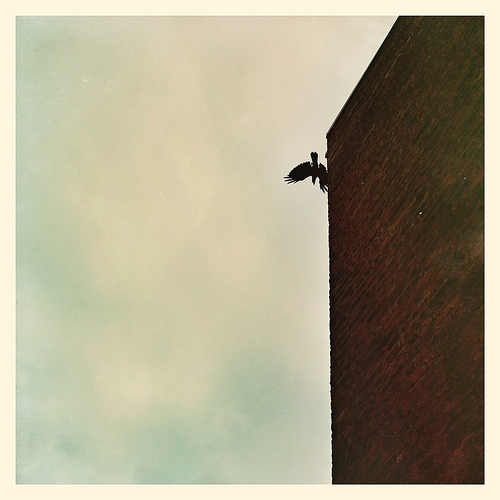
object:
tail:
[310, 151, 318, 168]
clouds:
[41, 49, 234, 408]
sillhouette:
[247, 191, 329, 269]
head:
[311, 175, 317, 186]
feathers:
[283, 173, 303, 184]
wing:
[283, 160, 311, 185]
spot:
[414, 203, 423, 222]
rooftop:
[305, 23, 473, 133]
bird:
[283, 150, 335, 196]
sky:
[10, 17, 330, 480]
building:
[326, 19, 483, 480]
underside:
[311, 157, 317, 179]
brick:
[342, 204, 481, 483]